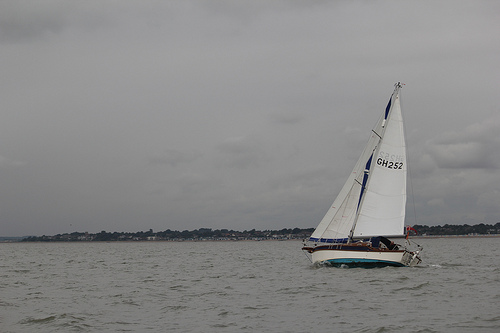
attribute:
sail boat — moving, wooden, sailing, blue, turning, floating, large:
[295, 78, 430, 270]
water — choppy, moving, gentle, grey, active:
[0, 236, 499, 331]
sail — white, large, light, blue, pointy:
[300, 80, 417, 241]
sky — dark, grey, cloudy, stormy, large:
[1, 1, 500, 236]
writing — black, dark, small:
[376, 158, 404, 172]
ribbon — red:
[403, 224, 417, 245]